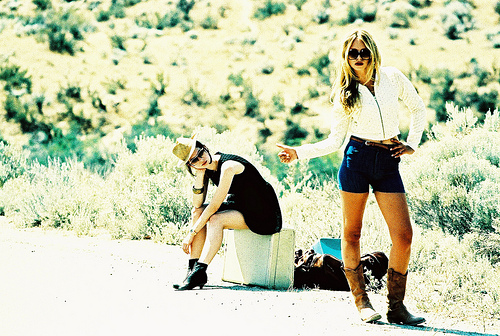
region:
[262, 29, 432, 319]
woman thumbing for a ride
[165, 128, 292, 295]
woman sitting on white suitcase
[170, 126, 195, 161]
hat of woman sitting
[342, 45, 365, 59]
sunglasses of woman standing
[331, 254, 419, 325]
brown boots of woman standing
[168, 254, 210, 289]
black booties of woman sitting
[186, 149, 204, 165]
sunglasses of woman sitting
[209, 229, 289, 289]
white suitcase woman is sitting on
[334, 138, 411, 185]
blue jean shorts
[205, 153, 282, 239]
black dress of woman sitting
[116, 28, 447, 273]
two women in the photo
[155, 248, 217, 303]
feet of the girl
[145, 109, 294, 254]
girl wearing a hat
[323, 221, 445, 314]
legs of the girl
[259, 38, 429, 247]
girl with her thumb out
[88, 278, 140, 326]
white street under girls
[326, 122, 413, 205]
shorts on the girl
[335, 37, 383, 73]
sunglasses on woman's face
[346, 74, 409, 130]
white shirt on lady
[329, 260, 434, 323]
brown boots on girl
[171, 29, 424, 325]
Two women hitchhicking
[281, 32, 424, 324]
woman standing up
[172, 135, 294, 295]
woman sitting on a suitcase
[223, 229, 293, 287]
white suitcase on the ground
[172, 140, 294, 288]
woman in a black dress and tan hat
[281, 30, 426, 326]
woman in jean shorts and brown cowboy boots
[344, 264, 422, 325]
brown cowboy boots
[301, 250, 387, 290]
brown bag on the ground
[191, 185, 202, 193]
bracelet on the sitting woman's wrist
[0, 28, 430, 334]
two women on the side of a road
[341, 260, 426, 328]
woman wearing brown cowboy boots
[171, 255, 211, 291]
woman wearing black ankle length boots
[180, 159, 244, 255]
woman's hand dangling near her ankle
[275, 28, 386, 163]
woman holding her thumb out in the gesture of one asking for a lift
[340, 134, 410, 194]
woman wearing tight fitting denim shorts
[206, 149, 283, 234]
woman wearing a short black dress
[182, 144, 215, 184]
woman's right hand is behind her neck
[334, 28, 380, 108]
woman has blonde highlights in her hair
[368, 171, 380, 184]
crotch area of woman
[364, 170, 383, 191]
vagina area of woman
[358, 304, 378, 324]
right foot of a woman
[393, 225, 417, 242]
left foot of a woman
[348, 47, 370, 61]
sunglasses on a woman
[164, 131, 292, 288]
woman sitting on a bag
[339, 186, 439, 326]
legs of a woman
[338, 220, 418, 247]
knees of a woman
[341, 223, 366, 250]
right knee of a woman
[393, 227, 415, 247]
left knee of woman